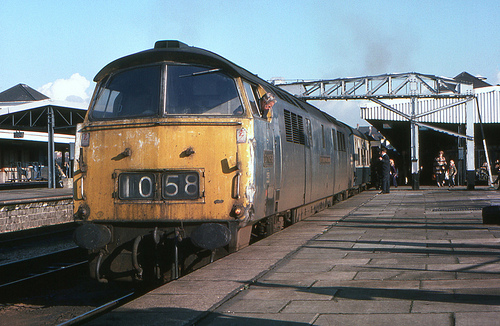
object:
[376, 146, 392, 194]
man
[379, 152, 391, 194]
suit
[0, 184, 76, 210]
pathway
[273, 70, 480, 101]
structure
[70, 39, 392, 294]
train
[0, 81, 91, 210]
station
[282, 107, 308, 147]
grate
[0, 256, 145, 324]
train tracks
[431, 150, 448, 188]
woman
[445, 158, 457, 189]
child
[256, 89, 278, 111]
head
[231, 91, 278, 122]
man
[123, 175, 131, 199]
number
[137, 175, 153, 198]
number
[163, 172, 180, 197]
number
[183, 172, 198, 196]
number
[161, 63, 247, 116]
windshields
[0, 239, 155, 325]
ground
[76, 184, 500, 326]
platform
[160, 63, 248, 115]
window